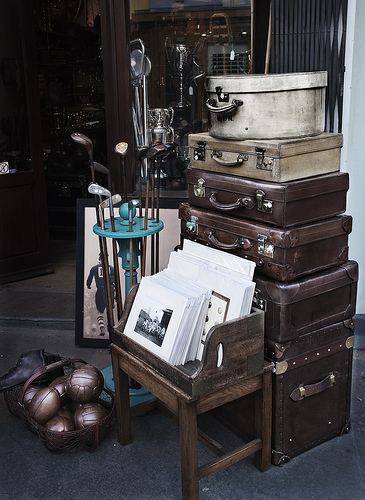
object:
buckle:
[212, 155, 243, 166]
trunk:
[187, 131, 341, 177]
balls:
[30, 387, 60, 422]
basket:
[5, 355, 115, 454]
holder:
[93, 195, 163, 322]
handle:
[206, 189, 255, 212]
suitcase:
[186, 173, 349, 229]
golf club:
[0, 0, 365, 500]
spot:
[197, 483, 209, 495]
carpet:
[94, 462, 156, 478]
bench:
[108, 342, 274, 500]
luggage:
[203, 72, 326, 136]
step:
[0, 317, 76, 321]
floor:
[46, 279, 69, 293]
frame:
[213, 292, 231, 303]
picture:
[75, 208, 175, 350]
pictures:
[123, 280, 186, 361]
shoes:
[0, 349, 45, 392]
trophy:
[144, 106, 174, 179]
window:
[124, 0, 250, 63]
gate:
[0, 78, 101, 131]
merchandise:
[125, 23, 200, 137]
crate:
[114, 279, 265, 395]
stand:
[110, 353, 131, 442]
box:
[208, 73, 327, 141]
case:
[161, 168, 180, 192]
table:
[145, 187, 190, 199]